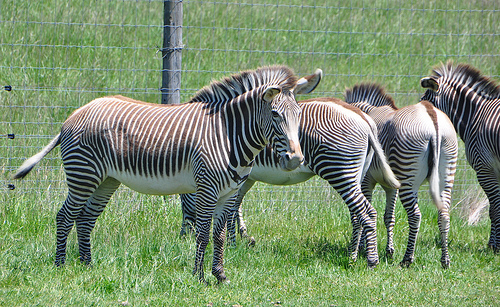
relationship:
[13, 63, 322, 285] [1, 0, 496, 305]
zebra standing in field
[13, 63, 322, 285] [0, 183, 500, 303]
zebra standing in field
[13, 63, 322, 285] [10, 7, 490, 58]
zebra standing in field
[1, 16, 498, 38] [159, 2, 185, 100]
wire attached to wooden pole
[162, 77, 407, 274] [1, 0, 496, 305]
zebra standing in field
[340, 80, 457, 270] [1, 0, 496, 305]
zebra standing in field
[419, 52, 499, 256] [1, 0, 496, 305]
zebra standing in field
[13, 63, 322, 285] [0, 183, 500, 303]
zebra in field